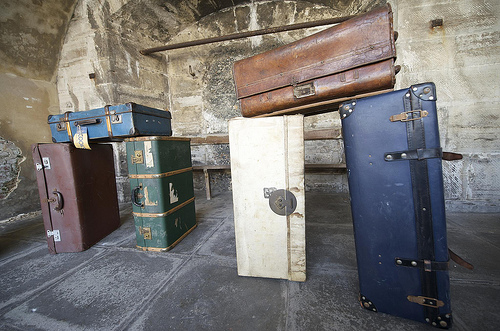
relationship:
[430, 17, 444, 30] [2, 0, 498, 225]
rust on wall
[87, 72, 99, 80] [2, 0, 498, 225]
rust on wall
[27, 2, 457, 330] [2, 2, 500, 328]
six in room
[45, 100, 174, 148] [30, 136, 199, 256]
suitcase on top of others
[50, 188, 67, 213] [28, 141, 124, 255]
handle on suitcase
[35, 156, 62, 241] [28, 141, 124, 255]
locks on suitcase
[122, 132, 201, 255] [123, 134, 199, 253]
suitcase has gold trim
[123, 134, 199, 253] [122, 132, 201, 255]
gold trim on suitcase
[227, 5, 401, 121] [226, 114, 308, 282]
suitcase on top of suitcase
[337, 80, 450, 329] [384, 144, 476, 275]
suitcase has straps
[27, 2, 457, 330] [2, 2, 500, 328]
suitcases in cave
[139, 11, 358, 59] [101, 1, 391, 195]
bar across alcove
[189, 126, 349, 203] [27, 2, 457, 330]
bench behind suitcases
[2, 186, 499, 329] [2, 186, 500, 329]
panels on floor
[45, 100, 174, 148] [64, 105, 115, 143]
suitcase has straps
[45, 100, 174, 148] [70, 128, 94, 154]
suitcase has tag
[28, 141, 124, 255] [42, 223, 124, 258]
suitcase on side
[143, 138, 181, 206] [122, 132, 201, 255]
labels on suitcase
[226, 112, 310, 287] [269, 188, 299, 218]
trunk has latch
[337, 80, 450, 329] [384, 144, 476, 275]
suitcase has black straps